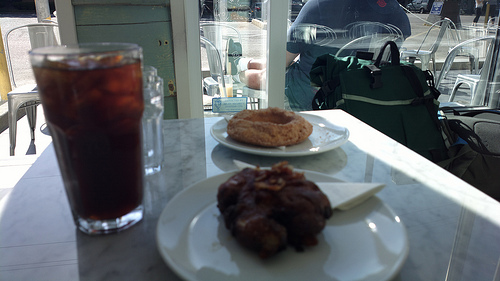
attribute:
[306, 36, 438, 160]
travel bag — green 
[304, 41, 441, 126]
bag — green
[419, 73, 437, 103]
strap — black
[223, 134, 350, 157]
plate — white 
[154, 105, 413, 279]
plates — white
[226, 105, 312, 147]
food — circular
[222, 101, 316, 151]
snack — brown 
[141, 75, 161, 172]
glass — small, empty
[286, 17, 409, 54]
glare — light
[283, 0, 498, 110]
glass — window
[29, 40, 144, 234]
glass — clear, filled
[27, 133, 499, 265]
countertop — white, marble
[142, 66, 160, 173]
clear glass — empty 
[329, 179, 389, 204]
napkin — white, folded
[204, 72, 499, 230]
table top — white 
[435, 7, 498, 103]
chair — white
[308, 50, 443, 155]
bag — black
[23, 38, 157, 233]
glass — full